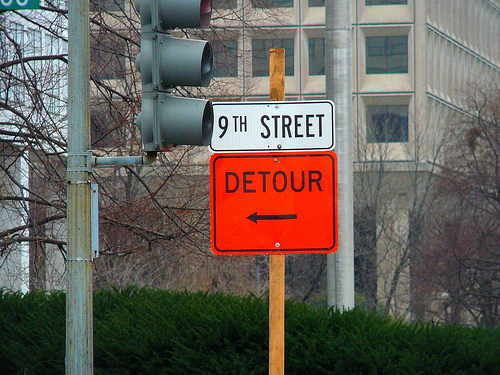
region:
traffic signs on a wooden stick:
[200, 44, 343, 373]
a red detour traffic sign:
[208, 149, 338, 252]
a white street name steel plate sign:
[207, 98, 336, 148]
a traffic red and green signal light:
[126, 2, 218, 166]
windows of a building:
[356, 25, 413, 76]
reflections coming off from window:
[357, 30, 412, 77]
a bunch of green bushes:
[4, 274, 498, 372]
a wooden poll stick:
[262, 261, 289, 373]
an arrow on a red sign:
[236, 204, 308, 229]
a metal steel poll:
[54, 2, 109, 370]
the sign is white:
[211, 100, 334, 151]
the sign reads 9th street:
[211, 100, 336, 151]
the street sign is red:
[210, 152, 336, 253]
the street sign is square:
[211, 150, 338, 253]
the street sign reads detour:
[209, 153, 336, 253]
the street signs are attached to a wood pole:
[210, 46, 339, 373]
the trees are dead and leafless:
[355, 66, 499, 323]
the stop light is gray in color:
[61, 0, 216, 374]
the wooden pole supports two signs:
[209, 48, 337, 373]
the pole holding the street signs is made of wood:
[212, 49, 337, 374]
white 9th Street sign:
[196, 73, 353, 151]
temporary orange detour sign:
[193, 150, 369, 277]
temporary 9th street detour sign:
[193, 47, 348, 309]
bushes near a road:
[3, 280, 496, 368]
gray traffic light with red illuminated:
[129, 0, 226, 159]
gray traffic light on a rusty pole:
[56, 2, 217, 372]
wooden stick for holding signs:
[246, 263, 348, 374]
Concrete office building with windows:
[351, 0, 498, 311]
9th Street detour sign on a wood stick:
[206, 46, 386, 373]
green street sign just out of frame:
[0, 0, 51, 21]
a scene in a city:
[18, 7, 490, 359]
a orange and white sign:
[194, 89, 368, 267]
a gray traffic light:
[44, 4, 216, 177]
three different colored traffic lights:
[133, 2, 220, 164]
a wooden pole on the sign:
[248, 39, 300, 301]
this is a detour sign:
[214, 101, 339, 266]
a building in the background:
[337, 16, 491, 302]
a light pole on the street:
[8, 27, 107, 372]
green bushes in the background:
[10, 272, 370, 374]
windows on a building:
[216, 9, 479, 173]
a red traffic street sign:
[202, 152, 343, 373]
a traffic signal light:
[48, 0, 218, 176]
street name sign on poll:
[204, 97, 341, 155]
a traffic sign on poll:
[189, 29, 350, 373]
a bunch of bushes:
[3, 273, 498, 373]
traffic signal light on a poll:
[53, 0, 203, 371]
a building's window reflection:
[352, 24, 417, 76]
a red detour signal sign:
[208, 153, 338, 258]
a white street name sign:
[207, 100, 337, 151]